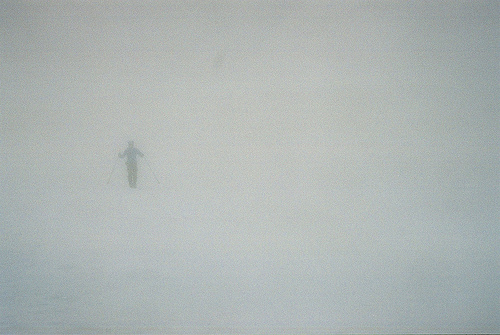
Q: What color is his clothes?
A: Black.